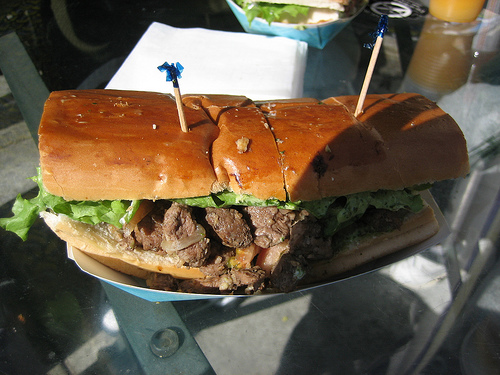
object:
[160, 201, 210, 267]
meat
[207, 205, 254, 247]
meat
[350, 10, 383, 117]
toothpic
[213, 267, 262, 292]
meat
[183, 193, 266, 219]
lettuce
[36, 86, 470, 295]
food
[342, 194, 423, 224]
lettuce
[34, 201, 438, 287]
bun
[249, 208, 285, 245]
beef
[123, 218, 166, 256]
meat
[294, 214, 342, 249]
meat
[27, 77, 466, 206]
bun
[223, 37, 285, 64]
napkins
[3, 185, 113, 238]
lettuce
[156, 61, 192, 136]
toothpick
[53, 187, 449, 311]
basket